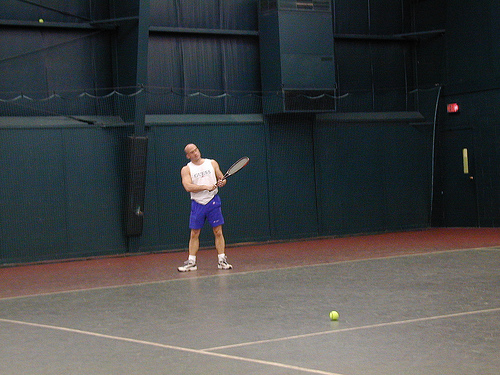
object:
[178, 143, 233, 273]
man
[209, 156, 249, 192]
racquet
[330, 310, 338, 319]
ball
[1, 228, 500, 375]
ground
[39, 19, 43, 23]
ball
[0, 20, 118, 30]
ledge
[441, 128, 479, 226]
door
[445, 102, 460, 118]
sign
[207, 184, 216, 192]
hands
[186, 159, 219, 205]
shirt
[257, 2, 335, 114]
vent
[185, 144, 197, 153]
bald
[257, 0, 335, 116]
green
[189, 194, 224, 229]
shorts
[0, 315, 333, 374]
lines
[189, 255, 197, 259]
white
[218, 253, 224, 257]
white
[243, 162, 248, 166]
red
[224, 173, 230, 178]
black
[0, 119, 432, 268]
foam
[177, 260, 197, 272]
shoes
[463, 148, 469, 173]
window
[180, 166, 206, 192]
arm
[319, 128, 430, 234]
wall